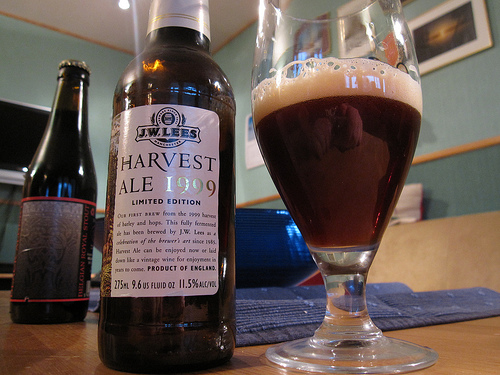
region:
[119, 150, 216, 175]
Black lettering on label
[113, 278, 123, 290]
Black numbers on bottle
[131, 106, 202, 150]
Black logo on bottle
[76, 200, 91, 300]
Red lettering on bottle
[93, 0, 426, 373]
Bottle next to wine glass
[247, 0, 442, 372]
Wine glass containing brown liquid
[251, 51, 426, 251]
Brown liquid with bubbles on top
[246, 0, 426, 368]
Wine glass with reflection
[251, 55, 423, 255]
Bubbles on top of brown liquid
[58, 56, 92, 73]
Silver top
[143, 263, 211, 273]
words on the label.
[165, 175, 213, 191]
numbers on the label.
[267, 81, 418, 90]
froth in the glass.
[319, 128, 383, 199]
beer in the glass.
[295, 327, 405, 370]
base of the glass.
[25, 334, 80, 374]
table made of wood.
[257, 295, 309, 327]
blue placemat on table.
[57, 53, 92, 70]
bottle cap on bottle.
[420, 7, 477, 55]
photo on the wall.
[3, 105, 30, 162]
screen near the wall.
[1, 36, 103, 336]
This is a bottle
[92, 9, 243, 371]
This is a bottle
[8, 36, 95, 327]
A very brown bottle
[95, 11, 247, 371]
A very brown bottle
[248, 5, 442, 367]
A glass of juice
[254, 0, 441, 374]
A glass of alcohol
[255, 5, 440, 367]
A glass with a drink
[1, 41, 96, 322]
A bottle with a drink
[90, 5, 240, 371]
A bottle with a drink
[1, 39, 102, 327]
A brown bottle with a drink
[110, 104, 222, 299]
White and black beer label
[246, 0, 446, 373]
Large glass of medium brown beer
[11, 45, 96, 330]
Dark brown bottle of beer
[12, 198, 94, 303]
Gray, red, and black label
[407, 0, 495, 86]
Framed picture on the wall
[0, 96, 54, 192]
Black and silver television in the background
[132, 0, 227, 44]
White and gold beer label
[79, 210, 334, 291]
Dark blue bowl behind bottles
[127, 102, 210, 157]
Black and white J.W. Lees logo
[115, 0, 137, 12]
Small bright white light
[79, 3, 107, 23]
this is the ceiling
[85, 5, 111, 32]
the ceiling is white in color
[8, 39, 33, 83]
this is the wall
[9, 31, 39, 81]
the wall is green in color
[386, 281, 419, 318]
this is a table mat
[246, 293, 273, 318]
the mat is blue in color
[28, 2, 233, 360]
these are two bottles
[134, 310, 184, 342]
the bottle is made of glass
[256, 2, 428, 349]
this is a glass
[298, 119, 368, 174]
the glass is full of wine